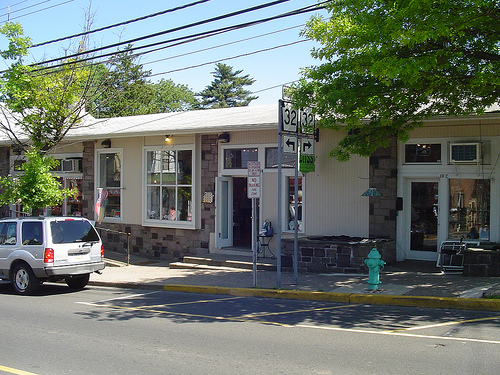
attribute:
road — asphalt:
[0, 282, 497, 374]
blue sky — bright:
[7, 4, 161, 58]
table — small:
[253, 231, 278, 256]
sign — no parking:
[245, 160, 260, 289]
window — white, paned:
[138, 143, 203, 230]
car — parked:
[3, 217, 103, 294]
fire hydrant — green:
[362, 246, 387, 291]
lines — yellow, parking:
[123, 279, 495, 326]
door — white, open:
[214, 175, 234, 248]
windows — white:
[91, 141, 204, 237]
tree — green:
[3, 22, 128, 214]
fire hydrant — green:
[358, 248, 387, 287]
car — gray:
[2, 209, 100, 291]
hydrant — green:
[319, 236, 426, 301]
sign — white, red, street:
[246, 158, 266, 196]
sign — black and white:
[276, 97, 299, 133]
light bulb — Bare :
[160, 135, 174, 147]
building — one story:
[9, 105, 497, 287]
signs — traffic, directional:
[279, 87, 321, 170]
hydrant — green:
[351, 216, 402, 331]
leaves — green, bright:
[6, 145, 75, 211]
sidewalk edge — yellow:
[167, 278, 498, 310]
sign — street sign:
[245, 161, 263, 198]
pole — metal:
[250, 198, 259, 285]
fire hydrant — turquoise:
[362, 246, 388, 287]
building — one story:
[44, 98, 498, 276]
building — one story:
[35, 93, 495, 286]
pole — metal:
[289, 102, 303, 298]